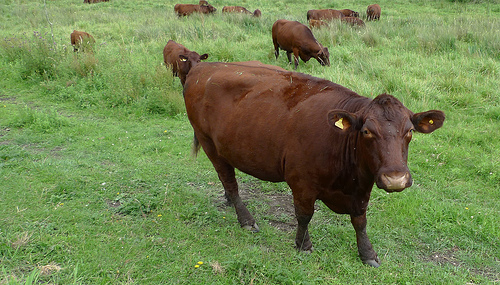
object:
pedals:
[361, 256, 381, 269]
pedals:
[296, 246, 315, 256]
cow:
[272, 19, 332, 70]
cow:
[366, 4, 381, 22]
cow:
[174, 4, 210, 18]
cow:
[222, 5, 254, 17]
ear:
[326, 109, 356, 135]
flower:
[195, 261, 204, 267]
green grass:
[2, 0, 497, 285]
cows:
[199, 0, 215, 14]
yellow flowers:
[223, 217, 226, 219]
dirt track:
[6, 128, 10, 131]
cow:
[70, 30, 95, 52]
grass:
[101, 18, 269, 40]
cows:
[254, 9, 261, 17]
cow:
[163, 40, 209, 77]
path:
[0, 128, 500, 285]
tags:
[429, 120, 434, 125]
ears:
[200, 53, 208, 60]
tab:
[335, 117, 344, 130]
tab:
[179, 59, 187, 62]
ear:
[412, 110, 445, 134]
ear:
[323, 47, 328, 51]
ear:
[179, 54, 188, 62]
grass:
[0, 73, 165, 285]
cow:
[309, 17, 367, 30]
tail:
[190, 132, 202, 159]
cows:
[81, 0, 113, 4]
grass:
[413, 160, 499, 285]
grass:
[0, 0, 71, 28]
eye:
[409, 130, 412, 132]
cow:
[180, 60, 446, 267]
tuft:
[378, 95, 397, 105]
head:
[325, 94, 447, 192]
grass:
[254, 0, 363, 8]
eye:
[364, 130, 368, 134]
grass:
[382, 0, 500, 92]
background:
[0, 0, 500, 61]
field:
[2, 0, 500, 285]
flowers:
[157, 214, 162, 216]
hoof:
[240, 223, 260, 233]